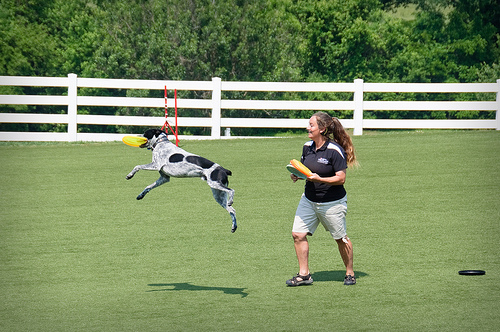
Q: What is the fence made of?
A: Wood.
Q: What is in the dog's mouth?
A: Frisbee.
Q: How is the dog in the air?
A: It jumped.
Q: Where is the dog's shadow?
A: On the grass.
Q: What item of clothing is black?
A: Girl's shirt.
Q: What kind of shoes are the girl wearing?
A: Sandals.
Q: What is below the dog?
A: Shadow.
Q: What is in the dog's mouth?
A: Frisbee.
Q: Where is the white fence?
A: Background.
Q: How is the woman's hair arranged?
A: Ponytail.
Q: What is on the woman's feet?
A: Sandals.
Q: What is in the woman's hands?
A: Frisbees.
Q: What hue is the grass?
A: Green.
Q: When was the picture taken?
A: Daytime.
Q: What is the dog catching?
A: A frisbee.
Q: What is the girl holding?
A: Frisbees.